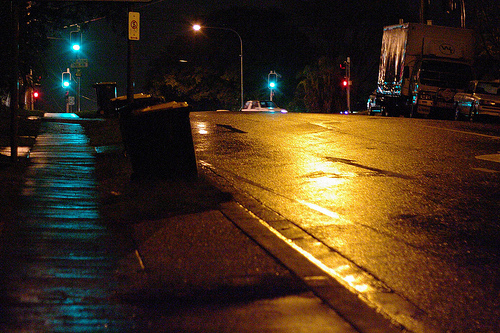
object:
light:
[33, 91, 40, 98]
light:
[341, 78, 350, 86]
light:
[269, 81, 277, 89]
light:
[72, 43, 81, 51]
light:
[63, 79, 70, 87]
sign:
[127, 12, 141, 42]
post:
[125, 1, 136, 117]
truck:
[377, 23, 478, 119]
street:
[188, 110, 499, 332]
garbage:
[127, 100, 201, 188]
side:
[0, 107, 404, 331]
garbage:
[92, 81, 116, 114]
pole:
[9, 2, 21, 159]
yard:
[0, 110, 43, 211]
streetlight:
[192, 23, 244, 113]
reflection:
[303, 155, 346, 186]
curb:
[210, 184, 384, 332]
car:
[238, 99, 290, 114]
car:
[455, 78, 499, 121]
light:
[193, 24, 202, 31]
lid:
[114, 96, 166, 111]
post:
[75, 24, 82, 115]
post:
[267, 70, 278, 103]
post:
[62, 68, 71, 114]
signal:
[339, 62, 346, 70]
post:
[343, 55, 351, 111]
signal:
[266, 72, 277, 93]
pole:
[238, 36, 247, 108]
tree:
[300, 57, 341, 113]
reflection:
[60, 112, 77, 118]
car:
[366, 88, 413, 117]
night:
[41, 1, 500, 333]